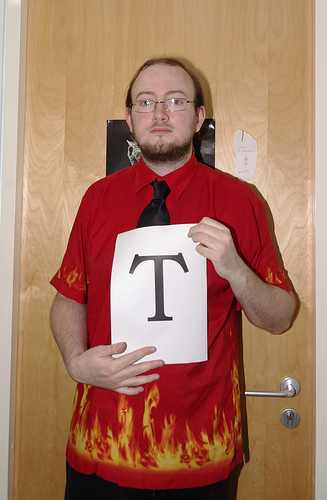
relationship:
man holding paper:
[46, 55, 301, 496] [117, 219, 219, 375]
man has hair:
[117, 48, 272, 396] [146, 56, 174, 70]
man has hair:
[117, 48, 272, 396] [139, 143, 180, 168]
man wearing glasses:
[117, 48, 272, 396] [120, 90, 202, 115]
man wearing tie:
[117, 48, 272, 396] [127, 171, 173, 225]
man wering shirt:
[117, 48, 272, 396] [76, 180, 243, 425]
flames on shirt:
[68, 398, 244, 478] [76, 180, 243, 425]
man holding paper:
[117, 48, 272, 396] [117, 219, 219, 375]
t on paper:
[132, 250, 189, 331] [117, 219, 219, 375]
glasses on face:
[120, 90, 202, 115] [126, 73, 194, 161]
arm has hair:
[46, 296, 95, 384] [50, 298, 75, 346]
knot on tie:
[142, 177, 176, 193] [127, 171, 173, 225]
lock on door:
[279, 406, 316, 438] [59, 28, 326, 499]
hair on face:
[139, 143, 180, 168] [126, 73, 194, 161]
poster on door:
[97, 115, 227, 170] [59, 28, 326, 499]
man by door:
[117, 48, 272, 396] [59, 28, 326, 499]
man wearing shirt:
[117, 48, 272, 396] [76, 180, 243, 425]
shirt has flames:
[76, 180, 243, 425] [68, 398, 244, 478]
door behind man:
[59, 28, 326, 499] [117, 48, 272, 396]